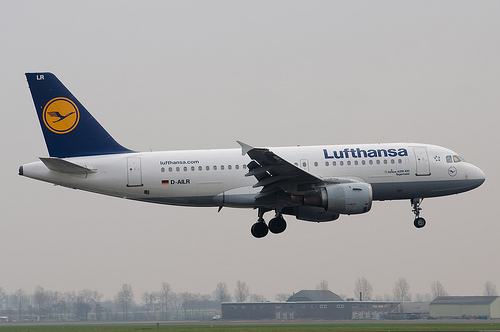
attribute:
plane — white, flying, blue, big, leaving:
[13, 62, 482, 226]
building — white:
[218, 285, 497, 324]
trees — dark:
[15, 284, 242, 321]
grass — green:
[118, 317, 391, 331]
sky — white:
[20, 10, 449, 231]